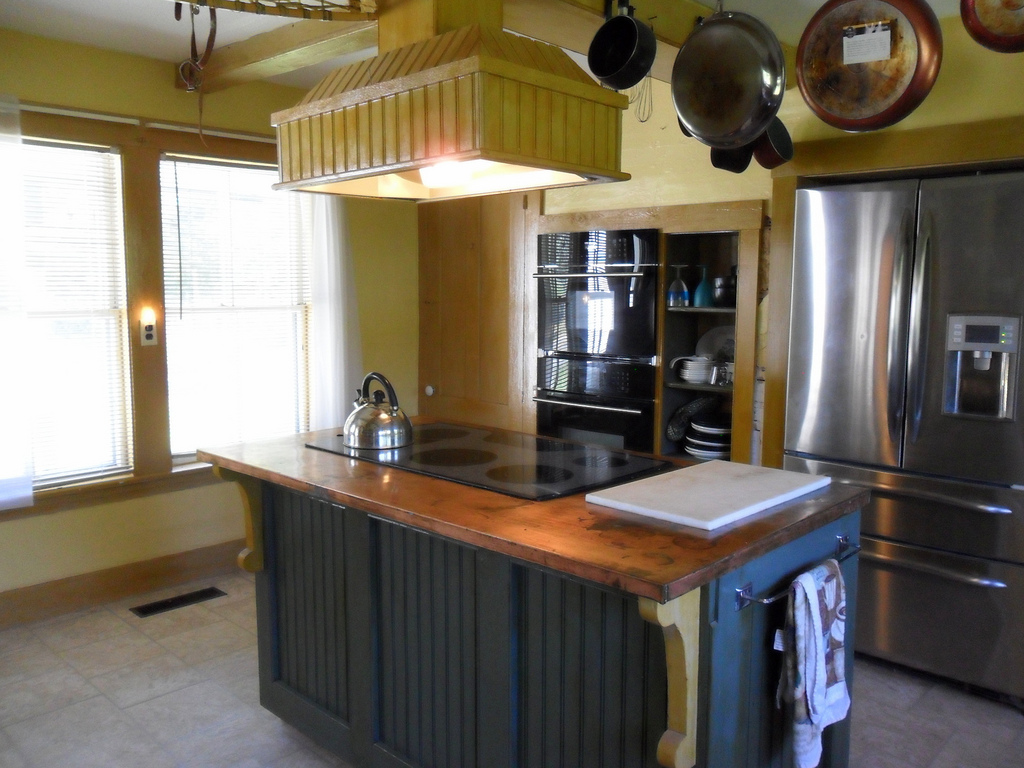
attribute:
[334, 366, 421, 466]
kettle — silver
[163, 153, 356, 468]
window — large kitchen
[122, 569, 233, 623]
vent — long, black, floor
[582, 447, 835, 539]
cutting board — long, white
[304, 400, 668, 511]
stove — flat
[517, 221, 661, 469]
wall oven — large, black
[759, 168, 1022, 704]
refrigerator — large, black, stainless steel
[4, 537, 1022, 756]
floor — white, tile, kitchen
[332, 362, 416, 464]
tea kettle — gray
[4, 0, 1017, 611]
wall — yellow painted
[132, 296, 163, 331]
light — bright, yellow